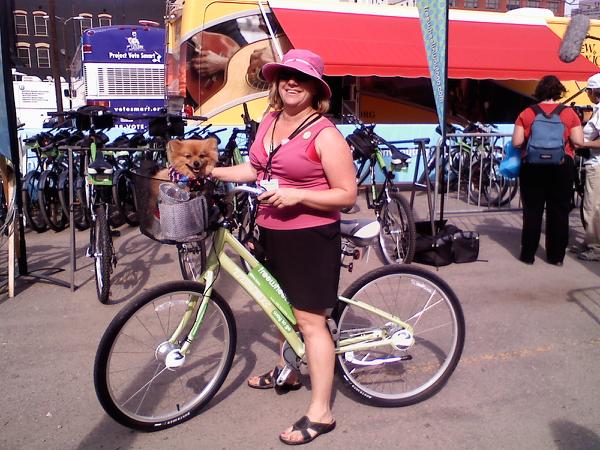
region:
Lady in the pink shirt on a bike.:
[206, 48, 356, 444]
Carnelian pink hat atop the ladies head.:
[261, 48, 329, 94]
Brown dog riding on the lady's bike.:
[165, 138, 219, 178]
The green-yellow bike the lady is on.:
[92, 225, 465, 433]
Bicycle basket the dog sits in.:
[127, 160, 226, 243]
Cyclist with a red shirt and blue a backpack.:
[513, 74, 584, 266]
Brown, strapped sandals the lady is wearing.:
[247, 364, 335, 448]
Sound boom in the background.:
[556, 14, 598, 62]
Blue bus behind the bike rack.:
[69, 26, 167, 131]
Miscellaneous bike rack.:
[22, 130, 180, 229]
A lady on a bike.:
[90, 48, 467, 445]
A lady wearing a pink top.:
[192, 45, 359, 447]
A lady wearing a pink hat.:
[202, 51, 363, 447]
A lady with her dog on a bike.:
[94, 47, 466, 445]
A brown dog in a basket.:
[133, 138, 221, 245]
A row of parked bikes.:
[22, 138, 146, 227]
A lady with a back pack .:
[503, 76, 582, 266]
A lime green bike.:
[91, 178, 464, 434]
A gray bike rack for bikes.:
[426, 126, 521, 213]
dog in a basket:
[138, 137, 223, 245]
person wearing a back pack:
[519, 68, 585, 268]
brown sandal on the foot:
[269, 405, 342, 448]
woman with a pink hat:
[216, 44, 357, 446]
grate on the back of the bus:
[77, 23, 166, 116]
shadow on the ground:
[535, 410, 598, 449]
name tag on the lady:
[258, 170, 281, 189]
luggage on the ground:
[420, 233, 480, 264]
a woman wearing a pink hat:
[249, 47, 335, 113]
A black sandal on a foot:
[275, 409, 343, 444]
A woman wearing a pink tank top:
[237, 35, 361, 247]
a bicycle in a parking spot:
[60, 139, 127, 308]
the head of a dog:
[158, 133, 226, 185]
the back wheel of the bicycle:
[333, 259, 467, 409]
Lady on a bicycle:
[79, 41, 472, 449]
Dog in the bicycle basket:
[126, 128, 229, 244]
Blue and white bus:
[54, 25, 166, 122]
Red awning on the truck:
[260, 2, 596, 95]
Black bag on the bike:
[342, 128, 382, 163]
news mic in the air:
[549, 6, 598, 73]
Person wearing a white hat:
[578, 68, 598, 109]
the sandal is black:
[280, 416, 336, 445]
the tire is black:
[333, 265, 465, 404]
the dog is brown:
[150, 136, 219, 209]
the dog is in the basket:
[126, 136, 218, 243]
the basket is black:
[128, 159, 214, 245]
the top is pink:
[249, 108, 340, 229]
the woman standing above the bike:
[94, 49, 465, 445]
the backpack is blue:
[527, 102, 568, 165]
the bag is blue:
[498, 142, 519, 179]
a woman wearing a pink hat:
[263, 47, 333, 107]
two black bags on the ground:
[419, 216, 487, 268]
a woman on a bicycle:
[217, 42, 349, 439]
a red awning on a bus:
[270, 2, 592, 91]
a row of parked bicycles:
[20, 126, 106, 205]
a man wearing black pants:
[521, 159, 577, 256]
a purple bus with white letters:
[76, 13, 168, 116]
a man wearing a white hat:
[583, 72, 597, 101]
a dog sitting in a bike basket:
[123, 137, 216, 240]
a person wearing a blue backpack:
[496, 76, 584, 267]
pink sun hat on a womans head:
[258, 44, 330, 101]